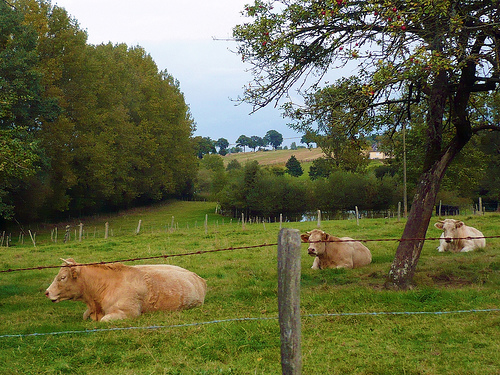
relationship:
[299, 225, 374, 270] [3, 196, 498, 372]
cows on grass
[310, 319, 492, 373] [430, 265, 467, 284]
grass on ground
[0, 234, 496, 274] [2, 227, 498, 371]
wire on fence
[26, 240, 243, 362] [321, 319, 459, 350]
cow laying on grass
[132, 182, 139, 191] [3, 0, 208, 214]
leaves on tree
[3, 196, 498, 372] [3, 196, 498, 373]
grass growing on ground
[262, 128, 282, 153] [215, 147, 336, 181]
tree on hillside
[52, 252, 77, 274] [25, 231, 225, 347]
horn on cow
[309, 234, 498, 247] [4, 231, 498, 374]
barb wire on fencing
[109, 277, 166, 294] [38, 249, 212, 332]
fur on cow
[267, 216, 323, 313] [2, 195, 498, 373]
post on fence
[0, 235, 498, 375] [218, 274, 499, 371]
fence on edge of field